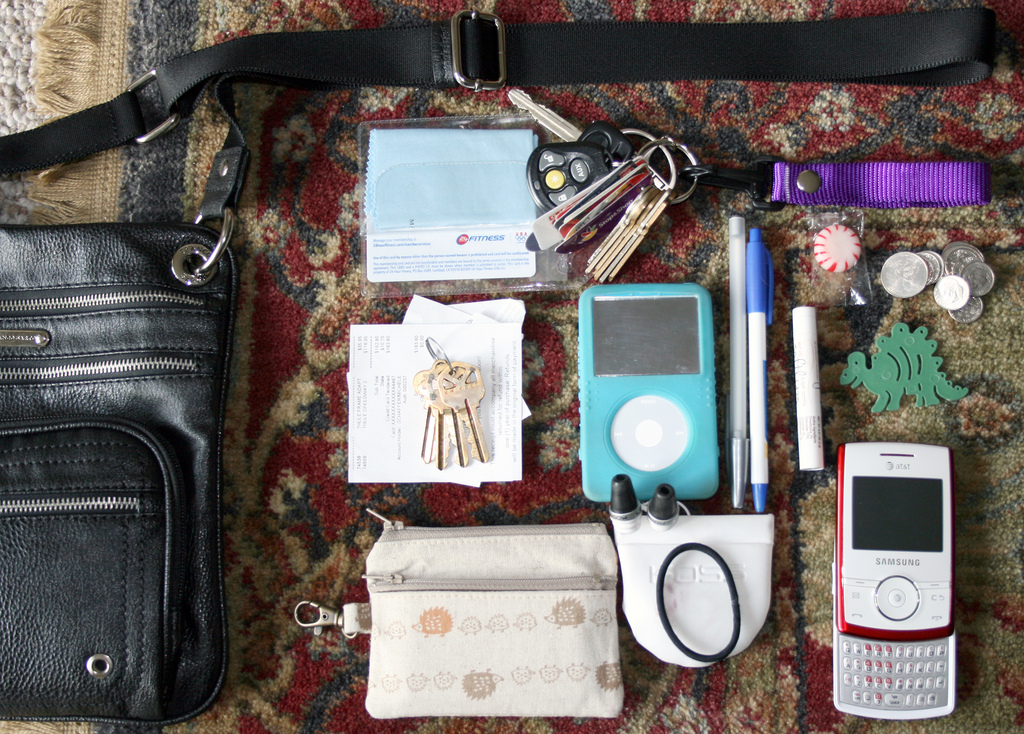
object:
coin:
[959, 261, 994, 298]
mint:
[813, 224, 863, 274]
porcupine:
[413, 606, 459, 636]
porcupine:
[457, 617, 482, 637]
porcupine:
[485, 614, 509, 633]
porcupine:
[512, 612, 539, 631]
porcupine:
[545, 597, 588, 629]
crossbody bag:
[0, 7, 992, 727]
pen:
[729, 215, 749, 510]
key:
[584, 186, 679, 284]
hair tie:
[655, 542, 742, 663]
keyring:
[425, 337, 452, 367]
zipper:
[0, 496, 145, 512]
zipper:
[2, 352, 208, 382]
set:
[413, 337, 490, 471]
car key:
[411, 361, 447, 465]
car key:
[430, 360, 457, 476]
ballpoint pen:
[744, 227, 776, 513]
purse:
[0, 215, 243, 727]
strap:
[0, 1, 997, 217]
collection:
[881, 241, 998, 323]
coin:
[881, 251, 928, 298]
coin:
[933, 276, 969, 313]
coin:
[944, 244, 987, 276]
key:
[506, 89, 634, 169]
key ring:
[506, 86, 993, 284]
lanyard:
[358, 112, 569, 299]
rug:
[236, 193, 337, 685]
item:
[830, 442, 956, 722]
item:
[685, 161, 989, 211]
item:
[840, 322, 969, 412]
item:
[607, 474, 776, 669]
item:
[293, 507, 624, 720]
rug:
[5, 0, 1023, 732]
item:
[347, 292, 533, 488]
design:
[400, 597, 592, 701]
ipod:
[580, 282, 722, 503]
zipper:
[361, 574, 615, 593]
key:
[458, 362, 490, 463]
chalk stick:
[791, 305, 826, 470]